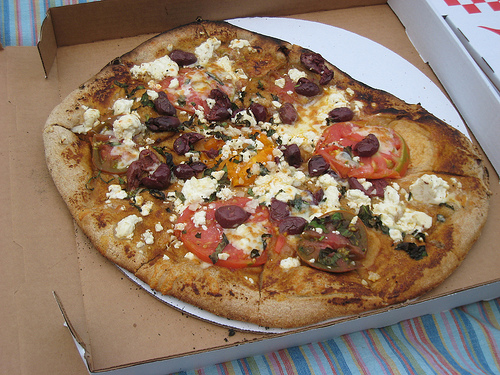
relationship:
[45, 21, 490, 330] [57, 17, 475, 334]
pizza on a plate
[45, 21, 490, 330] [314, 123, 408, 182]
pizza has a tomato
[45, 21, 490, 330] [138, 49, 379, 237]
pizza has olives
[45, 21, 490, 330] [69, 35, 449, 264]
pizza has cheese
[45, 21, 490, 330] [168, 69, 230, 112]
pizza has pepper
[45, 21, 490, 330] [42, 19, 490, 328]
pizza has crust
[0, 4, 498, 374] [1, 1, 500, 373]
box on a cloth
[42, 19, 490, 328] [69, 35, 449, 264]
crust has cheese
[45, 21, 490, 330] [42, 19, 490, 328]
pizza has a crust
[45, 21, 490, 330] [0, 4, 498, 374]
pizza i a box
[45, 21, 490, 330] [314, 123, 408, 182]
pizza has tomato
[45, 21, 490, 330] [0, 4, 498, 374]
pizza in a box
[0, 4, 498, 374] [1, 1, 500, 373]
box on cloth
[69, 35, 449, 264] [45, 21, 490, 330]
cheese on pizza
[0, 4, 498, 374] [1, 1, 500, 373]
box of cloth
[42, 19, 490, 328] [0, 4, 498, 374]
crust of box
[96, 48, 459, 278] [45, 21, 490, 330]
toppings are on a pizza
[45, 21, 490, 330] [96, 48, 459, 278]
pizza has toppings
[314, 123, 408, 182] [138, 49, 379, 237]
tomato has olives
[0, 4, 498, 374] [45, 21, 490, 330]
box has pizza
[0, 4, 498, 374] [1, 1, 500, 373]
box o a cloth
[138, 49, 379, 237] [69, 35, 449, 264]
olives are b cheese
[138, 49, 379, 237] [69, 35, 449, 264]
olives beside cheese